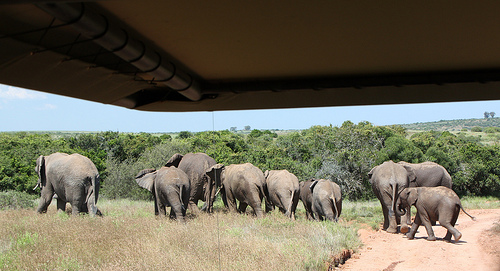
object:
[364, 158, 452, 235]
elephant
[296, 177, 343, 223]
elephant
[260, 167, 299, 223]
elephant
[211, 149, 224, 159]
leaf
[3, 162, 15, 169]
leaf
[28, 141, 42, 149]
leaf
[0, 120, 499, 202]
plant